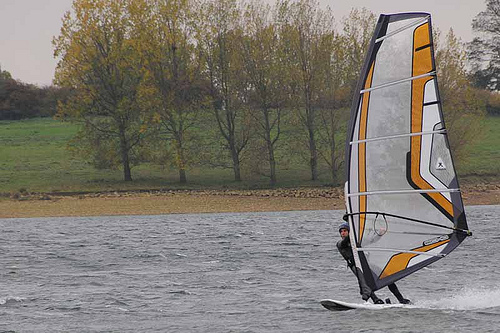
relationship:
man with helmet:
[323, 223, 418, 314] [338, 217, 350, 234]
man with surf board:
[323, 223, 418, 314] [312, 294, 431, 321]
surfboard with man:
[318, 297, 420, 310] [251, 50, 444, 303]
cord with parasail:
[341, 195, 466, 245] [361, 15, 481, 257]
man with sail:
[323, 223, 418, 314] [343, 11, 472, 301]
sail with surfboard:
[346, 9, 473, 296] [319, 299, 420, 311]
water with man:
[14, 233, 304, 326] [318, 193, 448, 294]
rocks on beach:
[105, 190, 345, 197] [2, 189, 342, 213]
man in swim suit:
[323, 223, 418, 314] [335, 241, 415, 306]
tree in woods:
[51, 1, 168, 184] [52, 2, 491, 181]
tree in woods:
[161, 22, 345, 212] [3, 1, 499, 201]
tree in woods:
[5, 78, 31, 122] [3, 1, 499, 201]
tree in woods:
[272, 5, 339, 185] [3, 1, 499, 201]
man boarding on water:
[323, 223, 418, 314] [2, 205, 484, 331]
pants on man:
[335, 262, 415, 308] [323, 223, 418, 314]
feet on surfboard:
[356, 281, 408, 304] [312, 293, 412, 313]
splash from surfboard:
[413, 283, 499, 313] [312, 290, 420, 316]